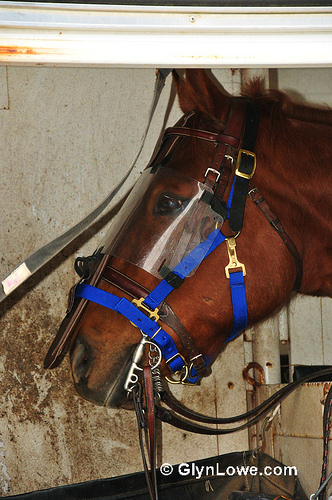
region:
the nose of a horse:
[60, 308, 126, 408]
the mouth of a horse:
[77, 307, 191, 441]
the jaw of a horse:
[195, 200, 314, 332]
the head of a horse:
[69, 163, 329, 432]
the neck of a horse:
[246, 138, 327, 340]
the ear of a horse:
[154, 41, 232, 127]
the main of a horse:
[232, 76, 329, 138]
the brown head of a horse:
[58, 104, 312, 395]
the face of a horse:
[55, 102, 287, 430]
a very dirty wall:
[1, 364, 71, 442]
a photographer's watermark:
[158, 447, 299, 488]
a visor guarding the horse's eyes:
[78, 154, 222, 291]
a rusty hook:
[246, 359, 281, 389]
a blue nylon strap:
[74, 288, 161, 339]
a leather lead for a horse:
[153, 381, 264, 433]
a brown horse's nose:
[45, 307, 142, 430]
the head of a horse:
[3, 41, 297, 441]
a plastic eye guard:
[104, 163, 227, 284]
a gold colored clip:
[220, 234, 251, 280]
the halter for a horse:
[55, 157, 263, 434]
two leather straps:
[154, 376, 321, 448]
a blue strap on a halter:
[224, 271, 253, 335]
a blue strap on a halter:
[135, 239, 220, 310]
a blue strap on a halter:
[78, 286, 203, 381]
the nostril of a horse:
[68, 341, 93, 381]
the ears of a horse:
[151, 67, 235, 120]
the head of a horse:
[97, 95, 325, 407]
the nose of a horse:
[60, 331, 95, 390]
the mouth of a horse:
[98, 350, 133, 406]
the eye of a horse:
[147, 190, 196, 218]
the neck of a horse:
[251, 210, 331, 343]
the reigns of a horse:
[116, 299, 201, 443]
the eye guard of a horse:
[118, 205, 197, 280]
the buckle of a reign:
[222, 152, 256, 181]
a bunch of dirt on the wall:
[20, 382, 101, 475]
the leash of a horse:
[13, 230, 69, 280]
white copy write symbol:
[158, 462, 173, 477]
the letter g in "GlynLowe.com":
[176, 462, 190, 475]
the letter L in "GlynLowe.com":
[215, 461, 224, 475]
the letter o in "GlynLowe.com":
[226, 466, 235, 475]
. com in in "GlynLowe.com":
[259, 464, 298, 475]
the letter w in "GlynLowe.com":
[234, 464, 250, 475]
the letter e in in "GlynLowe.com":
[249, 466, 258, 476]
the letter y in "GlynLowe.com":
[193, 464, 203, 480]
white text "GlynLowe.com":
[177, 460, 298, 477]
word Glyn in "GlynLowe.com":
[177, 461, 214, 479]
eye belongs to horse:
[145, 187, 188, 215]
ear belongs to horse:
[186, 67, 227, 120]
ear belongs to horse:
[170, 69, 201, 111]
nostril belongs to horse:
[69, 341, 89, 379]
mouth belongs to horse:
[102, 342, 143, 410]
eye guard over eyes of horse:
[90, 163, 224, 280]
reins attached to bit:
[119, 334, 329, 437]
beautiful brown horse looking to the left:
[68, 68, 332, 407]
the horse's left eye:
[153, 190, 188, 217]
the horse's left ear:
[183, 68, 230, 125]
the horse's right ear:
[170, 67, 197, 114]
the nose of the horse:
[67, 327, 108, 405]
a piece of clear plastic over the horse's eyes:
[93, 164, 222, 280]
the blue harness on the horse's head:
[74, 169, 249, 384]